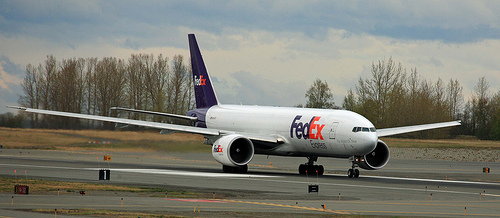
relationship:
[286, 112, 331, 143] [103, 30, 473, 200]
fedex on airplane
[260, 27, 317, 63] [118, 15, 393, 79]
clouds in sky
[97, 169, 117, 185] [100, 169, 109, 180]
sign says 1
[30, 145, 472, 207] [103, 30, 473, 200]
runway for airplane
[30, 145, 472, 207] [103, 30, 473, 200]
runway under airplane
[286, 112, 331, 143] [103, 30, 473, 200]
logo on airplane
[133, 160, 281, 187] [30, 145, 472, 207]
lines on road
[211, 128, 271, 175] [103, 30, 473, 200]
engine on airplane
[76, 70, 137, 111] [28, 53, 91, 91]
row of tree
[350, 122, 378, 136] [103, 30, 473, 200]
windows of airplane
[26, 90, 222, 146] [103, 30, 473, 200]
wing of airplane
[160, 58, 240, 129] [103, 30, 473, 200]
back of airplane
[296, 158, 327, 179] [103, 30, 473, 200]
wheels on airplane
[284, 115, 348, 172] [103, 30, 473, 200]
words on airplane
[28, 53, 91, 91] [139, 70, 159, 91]
tree without leaves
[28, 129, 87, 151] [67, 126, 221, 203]
grass on ground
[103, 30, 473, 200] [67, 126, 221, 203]
airplane on ground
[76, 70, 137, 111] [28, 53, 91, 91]
branches on tree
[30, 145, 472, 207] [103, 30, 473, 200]
roadway for airplane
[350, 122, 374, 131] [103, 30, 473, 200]
winshield on airplane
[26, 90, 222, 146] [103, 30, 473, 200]
wing on airplane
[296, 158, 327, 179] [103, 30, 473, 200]
wheels under airplane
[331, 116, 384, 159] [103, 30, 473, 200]
nose of airplane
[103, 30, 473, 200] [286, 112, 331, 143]
airplane from fedex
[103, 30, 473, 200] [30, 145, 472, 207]
airplane on tarmac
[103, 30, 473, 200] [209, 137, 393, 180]
airplane has engines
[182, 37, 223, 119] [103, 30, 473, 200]
tail of airplane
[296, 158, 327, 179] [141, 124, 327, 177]
wheels on groun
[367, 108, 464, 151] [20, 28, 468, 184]
left wing on airplane